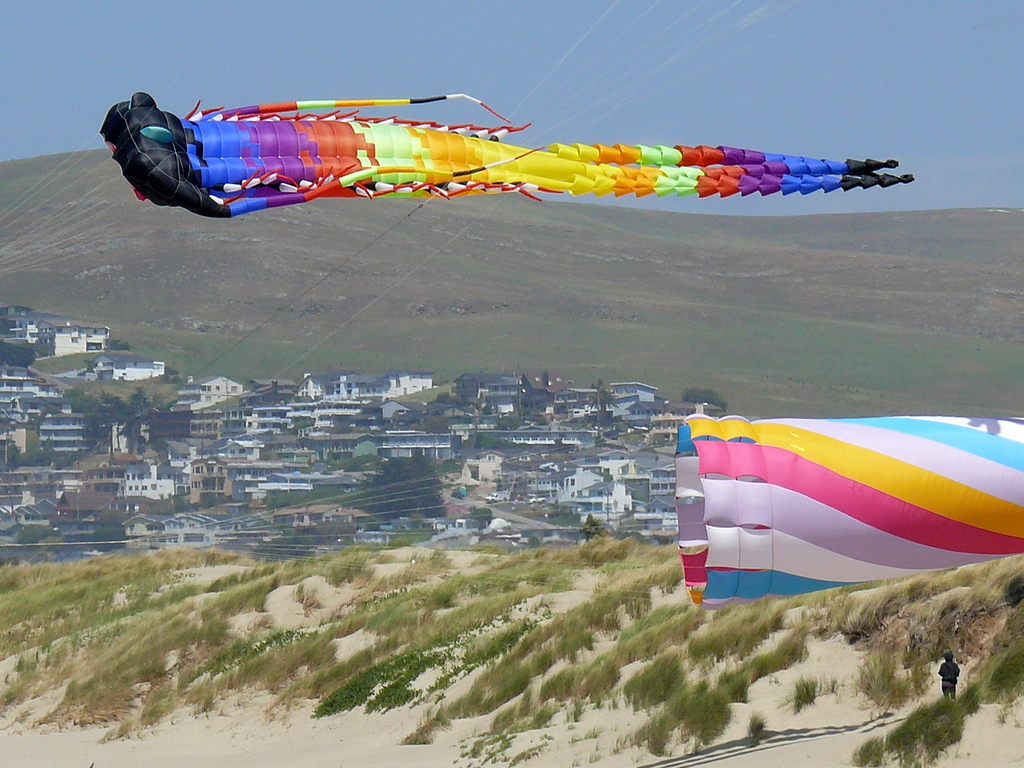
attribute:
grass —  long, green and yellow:
[501, 591, 547, 663]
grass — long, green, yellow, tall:
[2, 530, 1022, 764]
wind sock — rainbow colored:
[97, 87, 921, 219]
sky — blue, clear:
[2, 1, 1022, 213]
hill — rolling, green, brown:
[464, 549, 1018, 764]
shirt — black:
[941, 657, 963, 684]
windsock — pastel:
[669, 407, 1022, 608]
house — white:
[95, 353, 169, 380]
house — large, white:
[328, 364, 437, 395]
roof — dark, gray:
[308, 366, 436, 380]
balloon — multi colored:
[672, 409, 1022, 604]